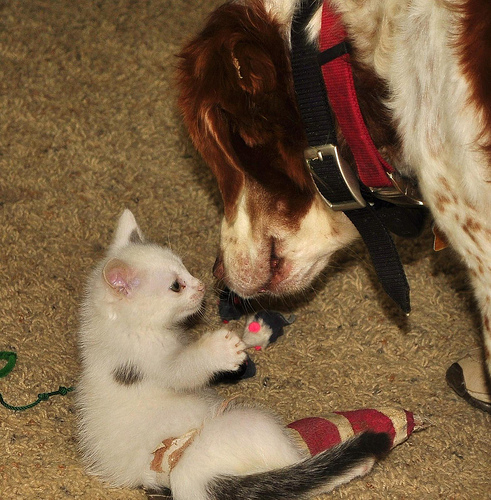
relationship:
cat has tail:
[65, 207, 391, 499] [195, 425, 395, 499]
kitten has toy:
[65, 207, 391, 499] [286, 406, 434, 464]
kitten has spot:
[65, 207, 391, 499] [109, 361, 152, 384]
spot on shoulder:
[109, 361, 152, 384] [87, 336, 178, 398]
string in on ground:
[0, 342, 73, 418] [6, 4, 228, 414]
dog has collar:
[172, 1, 490, 300] [291, 2, 365, 234]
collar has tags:
[289, 0, 410, 305] [424, 214, 450, 261]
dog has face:
[172, 1, 490, 300] [200, 47, 345, 306]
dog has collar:
[172, 1, 490, 300] [314, 6, 395, 202]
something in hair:
[224, 43, 269, 98] [225, 0, 304, 236]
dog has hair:
[172, 1, 490, 300] [225, 0, 304, 236]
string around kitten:
[0, 342, 73, 418] [65, 207, 391, 499]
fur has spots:
[92, 306, 169, 467] [109, 361, 152, 384]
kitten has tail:
[65, 207, 391, 499] [195, 425, 395, 499]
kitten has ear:
[65, 207, 391, 499] [99, 256, 139, 304]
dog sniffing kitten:
[172, 1, 490, 300] [65, 207, 391, 499]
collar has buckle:
[289, 0, 410, 305] [305, 141, 370, 213]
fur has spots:
[401, 9, 490, 226] [433, 169, 490, 247]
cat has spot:
[65, 207, 391, 499] [109, 361, 152, 384]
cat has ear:
[65, 207, 391, 499] [99, 256, 139, 304]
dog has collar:
[172, 1, 490, 300] [289, 0, 410, 305]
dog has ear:
[172, 1, 490, 300] [208, 28, 297, 149]